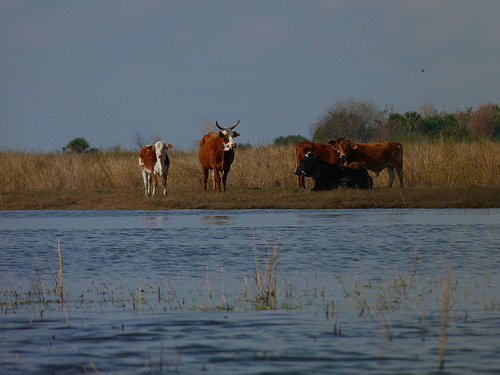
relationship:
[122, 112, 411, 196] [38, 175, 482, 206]
cows standing in river bed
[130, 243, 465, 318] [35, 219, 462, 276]
plants in water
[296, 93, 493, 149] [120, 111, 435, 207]
trees behind cows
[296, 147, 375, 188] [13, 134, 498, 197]
black cow laying on grass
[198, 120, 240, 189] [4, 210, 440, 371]
cow looking at water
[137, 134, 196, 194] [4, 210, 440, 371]
cow looking at water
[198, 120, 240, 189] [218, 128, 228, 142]
cow has spot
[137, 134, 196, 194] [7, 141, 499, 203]
cow on land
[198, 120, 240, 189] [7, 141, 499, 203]
cow on land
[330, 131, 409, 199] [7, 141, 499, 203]
cow on land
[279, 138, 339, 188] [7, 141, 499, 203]
cow on land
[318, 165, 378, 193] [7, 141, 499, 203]
cow on land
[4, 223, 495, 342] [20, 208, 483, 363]
grass sticking out of water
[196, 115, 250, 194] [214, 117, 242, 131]
cow has a spot has horns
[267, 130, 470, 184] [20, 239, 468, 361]
reeds growing water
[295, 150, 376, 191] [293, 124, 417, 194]
darker animal sits sits cows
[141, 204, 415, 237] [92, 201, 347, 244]
reflection of cows in water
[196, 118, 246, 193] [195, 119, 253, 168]
middle cattle figure wears expression